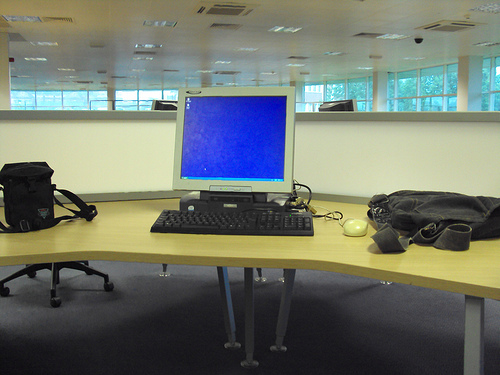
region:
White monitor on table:
[174, 84, 296, 198]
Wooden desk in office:
[21, 158, 498, 310]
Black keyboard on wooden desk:
[134, 205, 333, 240]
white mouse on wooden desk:
[338, 203, 384, 252]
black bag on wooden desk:
[3, 137, 101, 210]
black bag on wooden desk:
[370, 170, 498, 273]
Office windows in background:
[8, 64, 490, 122]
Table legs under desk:
[183, 260, 316, 368]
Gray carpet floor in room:
[10, 270, 379, 372]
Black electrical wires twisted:
[291, 188, 317, 223]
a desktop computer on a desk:
[150, 85, 366, 242]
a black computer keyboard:
[151, 208, 313, 239]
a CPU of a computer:
[179, 193, 284, 211]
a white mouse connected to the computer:
[343, 215, 365, 236]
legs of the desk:
[207, 266, 300, 368]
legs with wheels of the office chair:
[0, 264, 116, 307]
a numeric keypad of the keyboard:
[283, 213, 310, 232]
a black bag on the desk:
[366, 188, 496, 262]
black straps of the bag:
[370, 223, 472, 254]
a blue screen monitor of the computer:
[181, 95, 284, 181]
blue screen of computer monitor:
[186, 99, 281, 181]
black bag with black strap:
[4, 156, 94, 236]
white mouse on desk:
[340, 213, 367, 235]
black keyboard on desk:
[155, 206, 315, 234]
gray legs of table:
[215, 258, 489, 374]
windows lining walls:
[12, 75, 498, 109]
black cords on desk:
[279, 181, 342, 223]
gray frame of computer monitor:
[172, 83, 298, 198]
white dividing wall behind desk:
[7, 103, 489, 197]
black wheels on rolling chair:
[2, 265, 117, 308]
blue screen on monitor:
[158, 61, 318, 215]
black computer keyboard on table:
[139, 200, 337, 264]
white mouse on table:
[307, 193, 390, 265]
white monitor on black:
[157, 76, 321, 244]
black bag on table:
[6, 157, 135, 270]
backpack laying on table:
[368, 182, 498, 287]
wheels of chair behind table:
[4, 257, 145, 334]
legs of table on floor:
[138, 232, 370, 372]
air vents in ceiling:
[273, 17, 496, 75]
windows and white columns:
[344, 30, 494, 174]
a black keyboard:
[153, 203, 308, 244]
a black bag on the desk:
[5, 166, 63, 223]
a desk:
[81, 215, 139, 256]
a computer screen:
[178, 95, 288, 187]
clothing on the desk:
[373, 189, 482, 231]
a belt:
[375, 228, 469, 245]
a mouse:
[340, 213, 368, 237]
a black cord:
[297, 181, 314, 200]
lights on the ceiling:
[142, 13, 177, 33]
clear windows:
[389, 75, 449, 112]